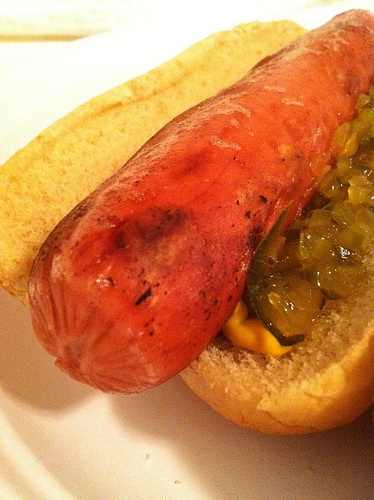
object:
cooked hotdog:
[28, 8, 374, 383]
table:
[0, 0, 372, 498]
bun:
[3, 0, 374, 440]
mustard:
[220, 279, 311, 357]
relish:
[245, 77, 373, 348]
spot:
[128, 141, 374, 344]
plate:
[0, 0, 372, 500]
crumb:
[268, 436, 369, 488]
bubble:
[276, 80, 307, 117]